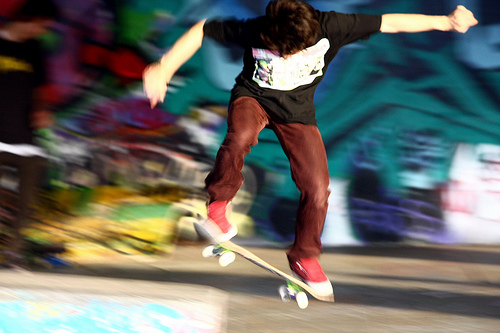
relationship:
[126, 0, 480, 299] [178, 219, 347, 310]
man on skateboard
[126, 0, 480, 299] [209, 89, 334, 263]
man wearing pants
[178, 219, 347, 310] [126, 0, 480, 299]
skateboard underneath man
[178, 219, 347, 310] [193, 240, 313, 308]
skateboard has wheels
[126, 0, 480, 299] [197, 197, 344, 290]
man wearing shoes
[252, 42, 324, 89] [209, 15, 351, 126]
logo on shirt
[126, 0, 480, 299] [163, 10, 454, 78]
man has arms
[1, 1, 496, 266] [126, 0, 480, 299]
background behind man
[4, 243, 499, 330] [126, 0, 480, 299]
ground below man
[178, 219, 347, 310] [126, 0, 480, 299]
skateboard under man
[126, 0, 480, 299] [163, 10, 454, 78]
man extending arms